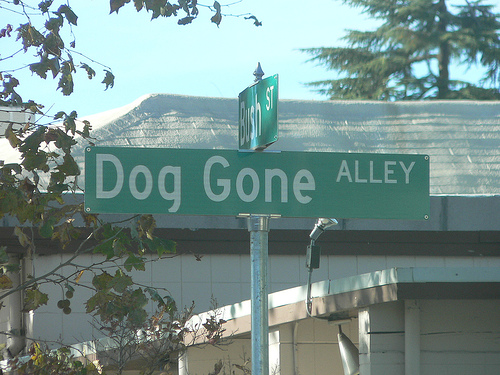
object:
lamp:
[336, 323, 360, 375]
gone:
[201, 154, 317, 205]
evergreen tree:
[297, 0, 499, 103]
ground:
[385, 154, 395, 159]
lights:
[309, 218, 339, 241]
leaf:
[140, 233, 180, 259]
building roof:
[46, 92, 497, 194]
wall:
[0, 258, 492, 350]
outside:
[0, 0, 499, 375]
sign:
[84, 146, 431, 222]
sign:
[236, 72, 279, 151]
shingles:
[192, 120, 231, 129]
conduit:
[306, 240, 322, 315]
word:
[94, 153, 182, 213]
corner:
[412, 241, 496, 372]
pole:
[241, 212, 283, 374]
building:
[0, 91, 496, 374]